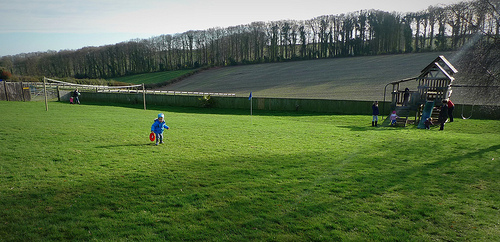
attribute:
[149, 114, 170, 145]
toddler — small, playing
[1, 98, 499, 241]
grass — green, thick, trimmed, cut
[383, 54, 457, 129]
playground — wooden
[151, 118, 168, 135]
jacket — blue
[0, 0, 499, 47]
sky — blue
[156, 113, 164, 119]
hat — blue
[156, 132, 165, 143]
pants — blue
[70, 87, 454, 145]
children — playing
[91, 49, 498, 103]
large hill — sloped, sloping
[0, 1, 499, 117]
trees — bare, lined, tall